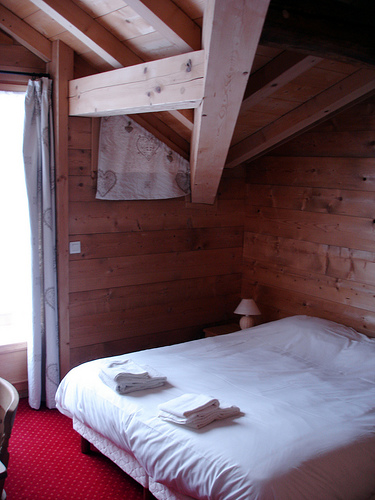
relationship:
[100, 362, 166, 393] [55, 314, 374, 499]
towels stacked on bed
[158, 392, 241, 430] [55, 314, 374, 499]
towels stacked on bed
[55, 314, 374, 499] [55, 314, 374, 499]
sheet layed out on bed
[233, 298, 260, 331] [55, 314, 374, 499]
lamp sitting by bed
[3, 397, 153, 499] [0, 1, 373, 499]
carpet on floor of room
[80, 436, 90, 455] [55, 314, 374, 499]
post for bed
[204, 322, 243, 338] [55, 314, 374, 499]
nightstand beside bed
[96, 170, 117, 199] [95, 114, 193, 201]
heart printed on curtain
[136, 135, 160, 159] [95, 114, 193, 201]
heart printed on curtain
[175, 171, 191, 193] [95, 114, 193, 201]
heart printed on curtain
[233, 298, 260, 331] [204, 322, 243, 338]
lamp sits on nightstand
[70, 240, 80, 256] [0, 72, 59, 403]
light switch to right of door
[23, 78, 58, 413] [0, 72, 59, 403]
curtain hanging to right of door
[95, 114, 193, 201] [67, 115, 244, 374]
curtain hung on wall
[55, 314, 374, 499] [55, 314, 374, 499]
sheet spread out on bed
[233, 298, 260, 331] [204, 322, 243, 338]
lamp sitting on nightstand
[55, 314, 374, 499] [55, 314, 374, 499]
bed covered with sheet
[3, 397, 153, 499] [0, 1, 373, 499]
carpet of room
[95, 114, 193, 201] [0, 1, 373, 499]
curtain hung in room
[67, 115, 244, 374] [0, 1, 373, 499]
wall of room